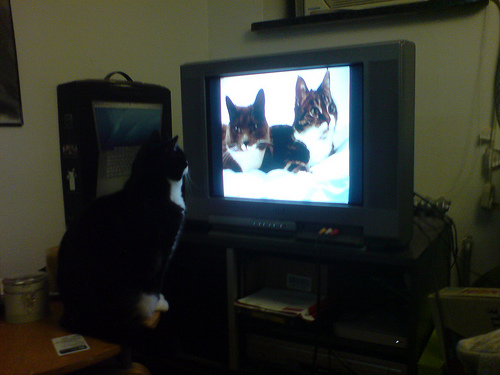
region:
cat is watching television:
[65, 36, 410, 273]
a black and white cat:
[41, 107, 228, 357]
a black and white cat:
[88, 107, 200, 315]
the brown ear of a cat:
[167, 133, 179, 149]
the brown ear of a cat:
[225, 96, 237, 111]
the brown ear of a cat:
[252, 88, 267, 104]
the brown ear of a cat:
[293, 75, 309, 100]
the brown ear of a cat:
[320, 69, 335, 89]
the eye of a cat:
[230, 121, 242, 133]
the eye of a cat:
[252, 121, 257, 130]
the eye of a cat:
[309, 107, 320, 114]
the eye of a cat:
[325, 101, 337, 112]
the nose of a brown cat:
[242, 137, 249, 146]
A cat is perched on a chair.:
[53, 125, 198, 337]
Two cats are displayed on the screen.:
[213, 76, 359, 203]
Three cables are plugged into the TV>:
[312, 221, 341, 244]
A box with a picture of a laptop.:
[51, 68, 177, 205]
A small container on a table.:
[6, 267, 50, 325]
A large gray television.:
[174, 52, 430, 243]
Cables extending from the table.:
[408, 193, 475, 269]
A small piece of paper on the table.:
[51, 335, 90, 358]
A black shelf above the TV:
[242, 5, 483, 33]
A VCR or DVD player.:
[331, 323, 423, 366]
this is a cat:
[95, 98, 229, 362]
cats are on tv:
[170, 120, 300, 269]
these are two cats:
[213, 119, 290, 204]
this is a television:
[211, 145, 434, 276]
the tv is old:
[233, 97, 385, 336]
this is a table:
[71, 302, 113, 373]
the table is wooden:
[39, 331, 91, 373]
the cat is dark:
[92, 197, 160, 307]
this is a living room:
[115, 173, 335, 365]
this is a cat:
[43, 105, 222, 347]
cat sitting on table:
[9, 101, 219, 372]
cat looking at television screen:
[33, 50, 433, 362]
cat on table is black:
[40, 101, 222, 365]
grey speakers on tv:
[129, 16, 437, 256]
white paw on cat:
[131, 244, 201, 359]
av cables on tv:
[305, 210, 362, 284]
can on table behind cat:
[5, 250, 65, 345]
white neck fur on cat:
[159, 167, 196, 227]